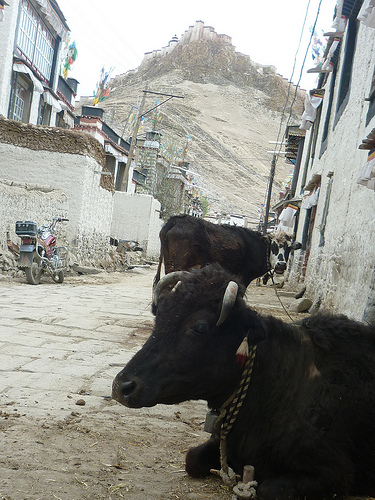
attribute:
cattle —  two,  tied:
[140, 222, 338, 428]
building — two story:
[279, 57, 371, 243]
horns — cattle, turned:
[137, 263, 247, 332]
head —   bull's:
[106, 251, 250, 419]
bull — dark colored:
[154, 214, 304, 296]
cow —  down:
[109, 264, 372, 499]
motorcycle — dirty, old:
[16, 214, 69, 283]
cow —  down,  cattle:
[315, 258, 364, 496]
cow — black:
[160, 207, 303, 300]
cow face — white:
[270, 223, 290, 285]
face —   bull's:
[111, 277, 217, 407]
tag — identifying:
[232, 335, 262, 371]